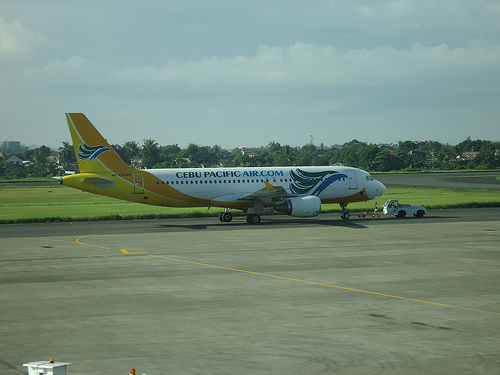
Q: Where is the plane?
A: On the tarmac.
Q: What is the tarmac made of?
A: Asphalt.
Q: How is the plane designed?
A: It is white with a gold and orange swirl at the tail's end.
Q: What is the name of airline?
A: The airline is Cebu Pacific Air.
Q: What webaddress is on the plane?
A: CebuPacificAir.com.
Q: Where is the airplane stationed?
A: At an airport.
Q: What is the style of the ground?
A: The ground consists of paved cement.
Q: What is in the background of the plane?
A: Flat grassland.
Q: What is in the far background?
A: A line of trees surround the runway area.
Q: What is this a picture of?
A: An airplane.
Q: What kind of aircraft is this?
A: A jet airplane.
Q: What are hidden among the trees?
A: Buildings.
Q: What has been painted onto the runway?
A: A yellow line and a yellow arrow.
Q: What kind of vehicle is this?
A: Airplane.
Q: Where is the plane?
A: Tarmac.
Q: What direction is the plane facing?
A: Right.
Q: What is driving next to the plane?
A: Service vehicle.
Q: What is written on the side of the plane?
A: Cebu pacific air.com.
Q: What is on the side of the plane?
A: Website address.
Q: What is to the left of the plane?
A: Green field.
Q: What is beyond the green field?
A: Tall trees.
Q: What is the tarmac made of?
A: Cement.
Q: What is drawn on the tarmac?
A: Yellow lines.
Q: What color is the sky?
A: Grey.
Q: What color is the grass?
A: Green.